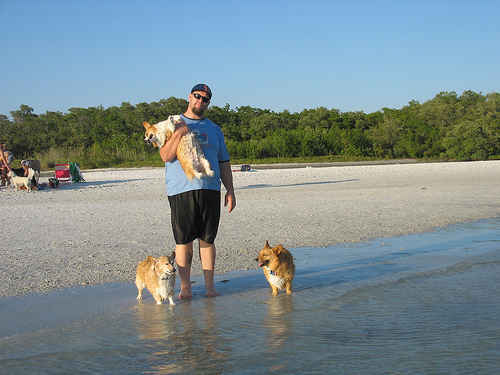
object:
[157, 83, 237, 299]
man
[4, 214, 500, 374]
water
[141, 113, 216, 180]
dog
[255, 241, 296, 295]
dog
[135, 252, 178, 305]
dog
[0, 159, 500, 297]
sand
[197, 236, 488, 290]
shadow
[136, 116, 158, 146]
head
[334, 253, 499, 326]
wave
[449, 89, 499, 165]
trees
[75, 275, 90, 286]
pebble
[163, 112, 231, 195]
shirt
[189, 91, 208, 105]
sunglasses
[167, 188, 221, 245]
shorts